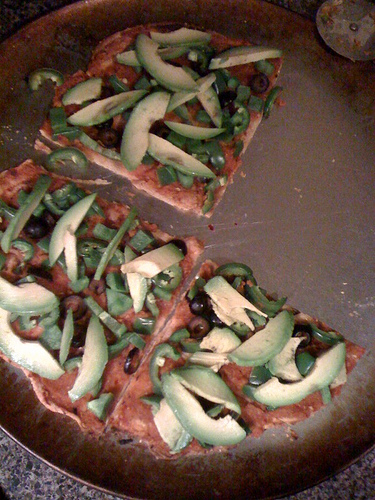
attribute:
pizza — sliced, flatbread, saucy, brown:
[35, 23, 287, 221]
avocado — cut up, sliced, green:
[132, 32, 202, 94]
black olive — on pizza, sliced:
[247, 73, 272, 96]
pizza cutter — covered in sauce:
[315, 1, 374, 61]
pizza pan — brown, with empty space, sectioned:
[1, 1, 373, 499]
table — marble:
[0, 1, 324, 46]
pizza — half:
[0, 159, 364, 463]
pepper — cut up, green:
[214, 262, 254, 278]